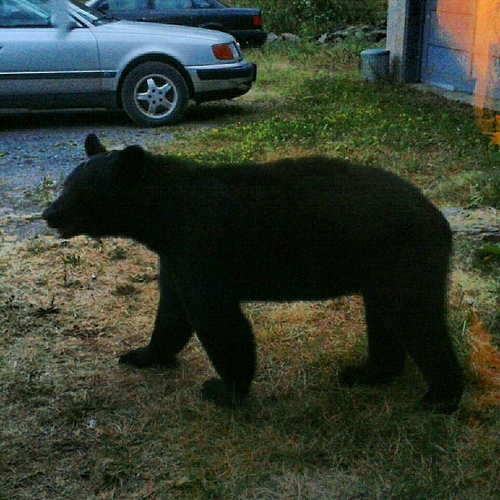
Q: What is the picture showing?
A: It is showing a field.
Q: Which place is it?
A: It is a field.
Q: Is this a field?
A: Yes, it is a field.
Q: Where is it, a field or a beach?
A: It is a field.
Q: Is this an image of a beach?
A: No, the picture is showing a field.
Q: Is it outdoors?
A: Yes, it is outdoors.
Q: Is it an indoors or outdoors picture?
A: It is outdoors.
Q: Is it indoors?
A: No, it is outdoors.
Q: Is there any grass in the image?
A: Yes, there is grass.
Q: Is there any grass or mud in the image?
A: Yes, there is grass.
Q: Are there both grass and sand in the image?
A: No, there is grass but no sand.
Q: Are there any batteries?
A: No, there are no batteries.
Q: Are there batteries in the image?
A: No, there are no batteries.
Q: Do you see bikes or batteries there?
A: No, there are no batteries or bikes.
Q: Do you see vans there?
A: No, there are no vans.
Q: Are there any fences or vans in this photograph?
A: No, there are no vans or fences.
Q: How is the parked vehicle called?
A: The vehicle is a car.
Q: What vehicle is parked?
A: The vehicle is a car.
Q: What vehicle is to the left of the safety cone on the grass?
A: The vehicle is a car.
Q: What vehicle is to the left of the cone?
A: The vehicle is a car.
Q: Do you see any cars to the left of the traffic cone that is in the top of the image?
A: Yes, there is a car to the left of the cone.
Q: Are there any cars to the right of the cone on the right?
A: No, the car is to the left of the cone.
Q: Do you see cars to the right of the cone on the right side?
A: No, the car is to the left of the cone.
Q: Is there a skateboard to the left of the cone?
A: No, there is a car to the left of the cone.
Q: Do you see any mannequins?
A: No, there are no mannequins.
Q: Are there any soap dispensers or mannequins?
A: No, there are no mannequins or soap dispensers.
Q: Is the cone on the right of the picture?
A: Yes, the cone is on the right of the image.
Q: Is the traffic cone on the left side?
A: No, the traffic cone is on the right of the image.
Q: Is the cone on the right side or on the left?
A: The cone is on the right of the image.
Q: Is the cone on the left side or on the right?
A: The cone is on the right of the image.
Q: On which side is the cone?
A: The cone is on the right of the image.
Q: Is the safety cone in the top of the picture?
A: Yes, the safety cone is in the top of the image.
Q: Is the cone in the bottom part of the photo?
A: No, the cone is in the top of the image.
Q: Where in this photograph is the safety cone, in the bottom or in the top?
A: The safety cone is in the top of the image.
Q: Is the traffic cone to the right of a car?
A: Yes, the traffic cone is to the right of a car.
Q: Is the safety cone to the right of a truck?
A: No, the safety cone is to the right of a car.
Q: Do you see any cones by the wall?
A: Yes, there is a cone by the wall.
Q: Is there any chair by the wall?
A: No, there is a cone by the wall.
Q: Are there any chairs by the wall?
A: No, there is a cone by the wall.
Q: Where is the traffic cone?
A: The traffic cone is on the grass.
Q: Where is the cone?
A: The traffic cone is on the grass.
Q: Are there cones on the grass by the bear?
A: Yes, there is a cone on the grass.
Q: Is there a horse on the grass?
A: No, there is a cone on the grass.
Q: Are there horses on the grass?
A: No, there is a cone on the grass.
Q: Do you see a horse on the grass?
A: No, there is a cone on the grass.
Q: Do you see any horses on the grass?
A: No, there is a cone on the grass.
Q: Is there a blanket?
A: No, there are no blankets.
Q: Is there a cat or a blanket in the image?
A: No, there are no blankets or cats.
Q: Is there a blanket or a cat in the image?
A: No, there are no blankets or cats.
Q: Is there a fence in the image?
A: No, there are no fences.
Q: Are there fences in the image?
A: No, there are no fences.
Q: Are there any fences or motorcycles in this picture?
A: No, there are no fences or motorcycles.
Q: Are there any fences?
A: No, there are no fences.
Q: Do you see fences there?
A: No, there are no fences.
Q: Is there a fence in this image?
A: No, there are no fences.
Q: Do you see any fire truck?
A: No, there are no fire trucks.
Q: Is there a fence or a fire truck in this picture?
A: No, there are no fire trucks or fences.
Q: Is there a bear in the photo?
A: Yes, there is a bear.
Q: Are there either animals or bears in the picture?
A: Yes, there is a bear.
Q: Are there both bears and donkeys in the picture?
A: No, there is a bear but no donkeys.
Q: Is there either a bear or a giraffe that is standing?
A: Yes, the bear is standing.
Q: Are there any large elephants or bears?
A: Yes, there is a large bear.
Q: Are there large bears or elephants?
A: Yes, there is a large bear.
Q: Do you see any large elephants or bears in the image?
A: Yes, there is a large bear.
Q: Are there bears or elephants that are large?
A: Yes, the bear is large.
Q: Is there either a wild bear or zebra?
A: Yes, there is a wild bear.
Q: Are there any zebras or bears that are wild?
A: Yes, the bear is wild.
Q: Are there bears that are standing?
A: Yes, there is a bear that is standing.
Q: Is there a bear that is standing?
A: Yes, there is a bear that is standing.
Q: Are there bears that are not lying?
A: Yes, there is a bear that is standing.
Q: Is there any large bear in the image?
A: Yes, there is a large bear.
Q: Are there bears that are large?
A: Yes, there is a bear that is large.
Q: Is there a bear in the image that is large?
A: Yes, there is a bear that is large.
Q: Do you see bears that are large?
A: Yes, there is a bear that is large.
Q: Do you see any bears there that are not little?
A: Yes, there is a large bear.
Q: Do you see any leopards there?
A: No, there are no leopards.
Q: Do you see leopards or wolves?
A: No, there are no leopards or wolves.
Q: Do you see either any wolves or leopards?
A: No, there are no leopards or wolves.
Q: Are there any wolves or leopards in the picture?
A: No, there are no leopards or wolves.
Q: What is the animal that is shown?
A: The animal is a bear.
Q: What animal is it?
A: The animal is a bear.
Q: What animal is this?
A: This is a bear.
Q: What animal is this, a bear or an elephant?
A: This is a bear.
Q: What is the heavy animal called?
A: The animal is a bear.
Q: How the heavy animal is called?
A: The animal is a bear.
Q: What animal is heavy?
A: The animal is a bear.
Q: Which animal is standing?
A: The animal is a bear.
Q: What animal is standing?
A: The animal is a bear.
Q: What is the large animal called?
A: The animal is a bear.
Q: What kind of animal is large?
A: The animal is a bear.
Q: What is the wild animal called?
A: The animal is a bear.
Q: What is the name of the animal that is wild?
A: The animal is a bear.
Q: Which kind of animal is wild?
A: The animal is a bear.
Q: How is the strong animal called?
A: The animal is a bear.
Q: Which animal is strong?
A: The animal is a bear.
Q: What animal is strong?
A: The animal is a bear.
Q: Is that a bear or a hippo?
A: That is a bear.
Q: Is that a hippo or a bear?
A: That is a bear.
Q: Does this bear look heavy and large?
A: Yes, the bear is heavy and large.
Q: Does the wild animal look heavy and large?
A: Yes, the bear is heavy and large.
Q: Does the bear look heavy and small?
A: No, the bear is heavy but large.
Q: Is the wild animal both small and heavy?
A: No, the bear is heavy but large.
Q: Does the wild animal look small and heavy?
A: No, the bear is heavy but large.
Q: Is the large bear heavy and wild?
A: Yes, the bear is heavy and wild.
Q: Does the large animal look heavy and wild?
A: Yes, the bear is heavy and wild.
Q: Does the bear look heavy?
A: Yes, the bear is heavy.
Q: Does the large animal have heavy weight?
A: Yes, the bear is heavy.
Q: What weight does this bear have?
A: The bear has heavy weight.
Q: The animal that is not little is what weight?
A: The bear is heavy.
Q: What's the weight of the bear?
A: The bear is heavy.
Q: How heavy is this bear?
A: The bear is heavy.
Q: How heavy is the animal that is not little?
A: The bear is heavy.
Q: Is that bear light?
A: No, the bear is heavy.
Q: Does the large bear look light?
A: No, the bear is heavy.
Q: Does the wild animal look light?
A: No, the bear is heavy.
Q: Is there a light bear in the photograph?
A: No, there is a bear but it is heavy.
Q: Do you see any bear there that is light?
A: No, there is a bear but it is heavy.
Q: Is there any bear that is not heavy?
A: No, there is a bear but it is heavy.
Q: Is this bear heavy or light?
A: The bear is heavy.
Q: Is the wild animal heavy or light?
A: The bear is heavy.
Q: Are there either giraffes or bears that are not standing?
A: No, there is a bear but it is standing.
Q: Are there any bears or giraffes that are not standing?
A: No, there is a bear but it is standing.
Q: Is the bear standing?
A: Yes, the bear is standing.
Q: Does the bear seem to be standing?
A: Yes, the bear is standing.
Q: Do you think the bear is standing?
A: Yes, the bear is standing.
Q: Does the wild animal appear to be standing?
A: Yes, the bear is standing.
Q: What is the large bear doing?
A: The bear is standing.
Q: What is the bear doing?
A: The bear is standing.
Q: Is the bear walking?
A: No, the bear is standing.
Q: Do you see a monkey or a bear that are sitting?
A: No, there is a bear but it is standing.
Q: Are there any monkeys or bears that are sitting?
A: No, there is a bear but it is standing.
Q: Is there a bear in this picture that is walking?
A: No, there is a bear but it is standing.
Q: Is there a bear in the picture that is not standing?
A: No, there is a bear but it is standing.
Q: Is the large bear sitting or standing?
A: The bear is standing.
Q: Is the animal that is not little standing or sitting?
A: The bear is standing.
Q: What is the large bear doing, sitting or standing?
A: The bear is standing.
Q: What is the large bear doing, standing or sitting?
A: The bear is standing.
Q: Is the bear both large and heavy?
A: Yes, the bear is large and heavy.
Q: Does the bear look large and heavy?
A: Yes, the bear is large and heavy.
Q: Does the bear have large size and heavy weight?
A: Yes, the bear is large and heavy.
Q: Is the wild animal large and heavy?
A: Yes, the bear is large and heavy.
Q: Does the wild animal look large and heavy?
A: Yes, the bear is large and heavy.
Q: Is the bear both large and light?
A: No, the bear is large but heavy.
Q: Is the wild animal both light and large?
A: No, the bear is large but heavy.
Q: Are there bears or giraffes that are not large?
A: No, there is a bear but it is large.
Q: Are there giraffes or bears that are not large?
A: No, there is a bear but it is large.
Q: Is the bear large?
A: Yes, the bear is large.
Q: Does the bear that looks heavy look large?
A: Yes, the bear is large.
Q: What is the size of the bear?
A: The bear is large.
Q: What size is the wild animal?
A: The bear is large.